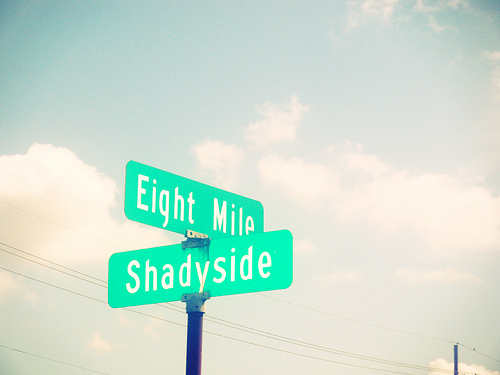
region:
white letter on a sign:
[253, 251, 274, 282]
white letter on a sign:
[237, 241, 258, 283]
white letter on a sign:
[225, 243, 238, 285]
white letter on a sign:
[212, 252, 227, 284]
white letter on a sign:
[192, 255, 213, 292]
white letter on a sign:
[174, 251, 196, 291]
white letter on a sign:
[158, 260, 177, 292]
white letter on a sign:
[142, 253, 161, 294]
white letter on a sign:
[122, 255, 142, 297]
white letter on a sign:
[205, 196, 230, 236]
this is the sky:
[30, 22, 142, 74]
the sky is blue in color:
[18, 27, 69, 65]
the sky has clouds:
[297, 123, 398, 228]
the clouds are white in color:
[8, 156, 79, 216]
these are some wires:
[254, 312, 364, 372]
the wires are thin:
[263, 313, 390, 360]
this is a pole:
[180, 296, 207, 360]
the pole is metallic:
[185, 320, 212, 370]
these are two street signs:
[95, 162, 288, 299]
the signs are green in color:
[214, 230, 223, 247]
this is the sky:
[91, 27, 191, 86]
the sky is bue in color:
[126, 38, 226, 105]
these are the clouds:
[326, 186, 401, 246]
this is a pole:
[447, 340, 466, 373]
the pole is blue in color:
[447, 345, 462, 364]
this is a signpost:
[137, 244, 257, 298]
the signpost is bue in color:
[110, 265, 115, 295]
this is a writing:
[133, 249, 265, 292]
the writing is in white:
[141, 257, 239, 282]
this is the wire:
[305, 333, 352, 363]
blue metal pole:
[186, 313, 202, 373]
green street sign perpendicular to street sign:
[125, 159, 266, 240]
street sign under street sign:
[108, 228, 294, 310]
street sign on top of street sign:
[126, 158, 263, 240]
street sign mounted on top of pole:
[105, 228, 295, 306]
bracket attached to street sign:
[181, 290, 210, 310]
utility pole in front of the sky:
[452, 343, 458, 374]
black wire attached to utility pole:
[261, 290, 499, 367]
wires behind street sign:
[1, 243, 106, 309]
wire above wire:
[3, 198, 129, 251]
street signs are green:
[106, 161, 295, 305]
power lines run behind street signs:
[0, 197, 499, 374]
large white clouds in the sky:
[1, 90, 499, 373]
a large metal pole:
[183, 293, 208, 373]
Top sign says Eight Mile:
[134, 170, 254, 237]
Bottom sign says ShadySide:
[120, 243, 273, 295]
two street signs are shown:
[109, 154, 291, 311]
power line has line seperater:
[448, 338, 463, 372]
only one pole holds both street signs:
[181, 288, 211, 373]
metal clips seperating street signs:
[181, 227, 212, 249]